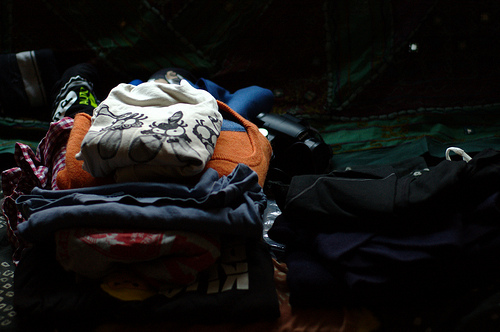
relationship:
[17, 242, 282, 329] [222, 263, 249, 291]
shirt with letter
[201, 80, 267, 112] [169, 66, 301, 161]
cloth on pile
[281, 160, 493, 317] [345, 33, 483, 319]
shirt on right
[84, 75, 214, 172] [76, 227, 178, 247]
shirt on shirt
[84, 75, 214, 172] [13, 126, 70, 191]
shirt on shirt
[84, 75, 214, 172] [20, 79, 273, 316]
shirt on pile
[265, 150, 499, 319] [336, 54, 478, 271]
shirt on right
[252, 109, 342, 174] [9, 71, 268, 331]
camera next to shirts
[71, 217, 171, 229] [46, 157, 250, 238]
edge of a towel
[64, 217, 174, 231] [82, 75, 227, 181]
edge of a cloth